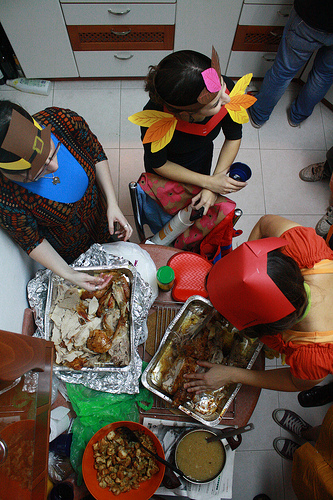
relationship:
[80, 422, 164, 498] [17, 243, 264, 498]
bowl on table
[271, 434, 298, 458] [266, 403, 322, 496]
shoe of person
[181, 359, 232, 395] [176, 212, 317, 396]
hand of a person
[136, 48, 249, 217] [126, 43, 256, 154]
person in a costume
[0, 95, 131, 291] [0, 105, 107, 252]
person in a costume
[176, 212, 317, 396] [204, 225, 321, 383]
person in a costume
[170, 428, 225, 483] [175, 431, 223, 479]
bowl of gravy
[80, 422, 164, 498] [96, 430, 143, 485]
bowl of food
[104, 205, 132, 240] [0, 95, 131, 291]
hand of a person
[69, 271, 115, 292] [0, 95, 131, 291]
hand of a person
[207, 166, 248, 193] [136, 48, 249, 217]
hand of a person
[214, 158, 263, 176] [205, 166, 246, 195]
cup in right hand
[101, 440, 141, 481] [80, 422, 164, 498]
food in bowl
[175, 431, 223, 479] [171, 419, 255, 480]
gravy in cooking pot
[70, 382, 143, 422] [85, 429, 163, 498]
plastic bag under bowl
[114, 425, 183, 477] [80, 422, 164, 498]
spoon in bowl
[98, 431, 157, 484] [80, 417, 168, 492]
food in bowl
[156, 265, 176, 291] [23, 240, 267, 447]
container on table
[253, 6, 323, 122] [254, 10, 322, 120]
person standing by cabinets wearing blue jeans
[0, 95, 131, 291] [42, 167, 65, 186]
person on left wearing a necklace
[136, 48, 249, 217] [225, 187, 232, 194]
person wearing a ring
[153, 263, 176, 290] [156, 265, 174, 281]
container with  a lid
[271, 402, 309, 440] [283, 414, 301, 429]
shoe with laces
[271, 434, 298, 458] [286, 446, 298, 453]
shoe with laces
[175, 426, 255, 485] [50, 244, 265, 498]
cooking pot on table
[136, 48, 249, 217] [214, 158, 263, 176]
person with cup